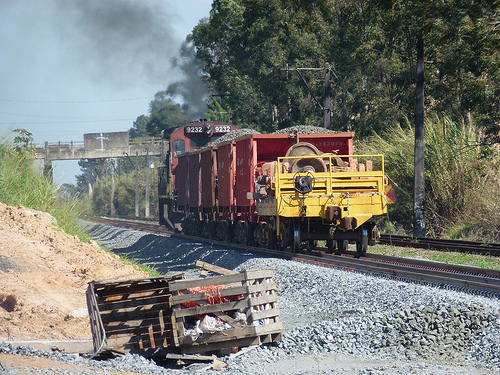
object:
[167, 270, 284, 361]
crate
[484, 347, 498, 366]
gravel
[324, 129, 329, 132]
gravel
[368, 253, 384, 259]
train tracks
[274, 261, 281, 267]
rocks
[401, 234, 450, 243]
tracks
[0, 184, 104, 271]
hill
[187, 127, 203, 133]
numbers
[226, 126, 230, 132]
numbers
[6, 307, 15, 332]
dirt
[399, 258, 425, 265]
tracks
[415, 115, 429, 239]
trunk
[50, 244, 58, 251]
tan dirt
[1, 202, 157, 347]
dirt mound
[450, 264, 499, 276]
tracks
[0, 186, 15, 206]
grass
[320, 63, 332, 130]
post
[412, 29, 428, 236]
post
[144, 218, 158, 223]
train tracks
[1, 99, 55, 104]
power lines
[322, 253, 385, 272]
track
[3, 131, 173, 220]
bridge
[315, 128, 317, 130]
gravel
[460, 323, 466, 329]
rocks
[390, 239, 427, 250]
tracks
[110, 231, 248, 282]
shadow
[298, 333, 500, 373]
ground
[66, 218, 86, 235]
grass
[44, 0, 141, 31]
smoke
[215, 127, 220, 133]
numbers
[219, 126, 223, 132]
numbers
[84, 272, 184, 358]
crate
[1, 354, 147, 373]
ground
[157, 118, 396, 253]
car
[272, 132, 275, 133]
gravel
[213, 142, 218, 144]
gravel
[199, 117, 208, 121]
smoke stack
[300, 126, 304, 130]
gravel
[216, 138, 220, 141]
gravel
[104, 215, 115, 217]
train track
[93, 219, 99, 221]
train track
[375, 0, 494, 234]
tree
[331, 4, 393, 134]
tree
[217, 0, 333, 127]
tree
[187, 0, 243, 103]
tree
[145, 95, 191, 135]
tree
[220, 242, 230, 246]
track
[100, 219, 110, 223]
track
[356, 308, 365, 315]
rock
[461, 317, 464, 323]
rock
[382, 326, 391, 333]
rock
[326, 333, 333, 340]
rock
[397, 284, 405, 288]
rock